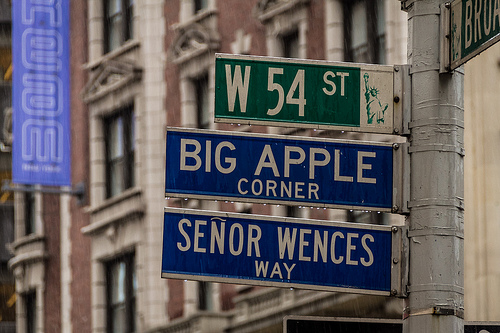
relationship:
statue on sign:
[355, 76, 392, 118] [207, 51, 407, 135]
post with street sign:
[129, 72, 169, 219] [161, 210, 401, 299]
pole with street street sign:
[401, 0, 462, 330] [211, 53, 402, 134]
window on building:
[101, 100, 136, 199] [1, 0, 402, 331]